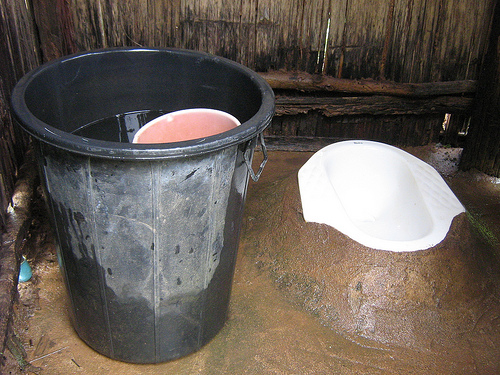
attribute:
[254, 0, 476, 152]
wood — rotten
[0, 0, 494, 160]
wall — wood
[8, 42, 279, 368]
garbage can — black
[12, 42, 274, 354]
trash can — large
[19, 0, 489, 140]
wood — rotten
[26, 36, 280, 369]
bucket — black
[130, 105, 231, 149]
object — white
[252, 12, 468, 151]
wood — rotten, water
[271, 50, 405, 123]
rotten wood — from water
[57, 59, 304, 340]
bucket — black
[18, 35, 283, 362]
garbage — black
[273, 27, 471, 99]
wood — rotten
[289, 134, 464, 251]
hole — white